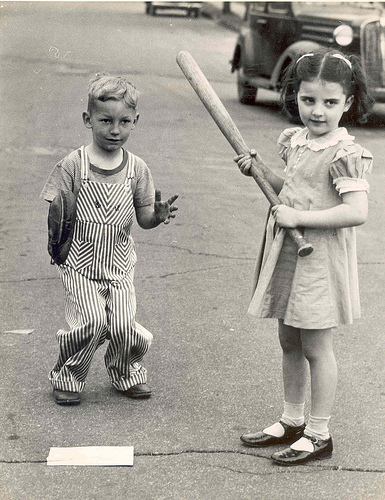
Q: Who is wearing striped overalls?
A: A boy.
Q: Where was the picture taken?
A: On a street.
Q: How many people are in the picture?
A: 2.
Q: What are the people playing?
A: Baseball.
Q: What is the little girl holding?
A: A bat.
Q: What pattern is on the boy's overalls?
A: Stripes.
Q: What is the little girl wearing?
A: A dress.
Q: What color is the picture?
A: Black and white.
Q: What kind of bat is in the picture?
A: Wooden.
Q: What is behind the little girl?
A: A car.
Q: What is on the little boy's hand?
A: A glove.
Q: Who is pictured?
A: A young boy and young girl.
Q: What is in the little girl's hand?
A: A baseball bat.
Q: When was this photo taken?
A: In the 50's-60's.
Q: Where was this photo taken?
A: On a street.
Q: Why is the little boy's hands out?
A: To play the catcher.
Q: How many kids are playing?
A: Just 2.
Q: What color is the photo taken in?
A: Black and white.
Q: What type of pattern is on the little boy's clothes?
A: Stripes.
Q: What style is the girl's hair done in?
A: Pigtails.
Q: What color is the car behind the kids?
A: Black.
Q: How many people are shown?
A: 2.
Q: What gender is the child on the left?
A: Male.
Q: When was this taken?
A: During the day.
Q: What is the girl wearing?
A: A dress.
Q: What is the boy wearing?
A: Overalls.